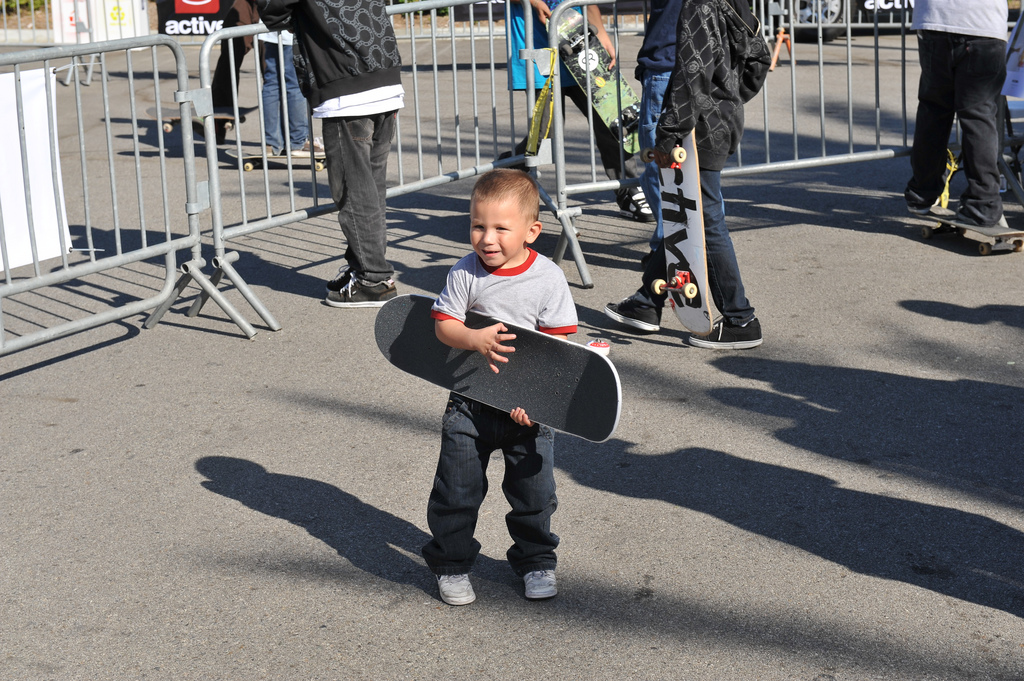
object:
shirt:
[442, 243, 581, 346]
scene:
[0, 0, 1024, 681]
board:
[371, 290, 628, 448]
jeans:
[414, 374, 557, 574]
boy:
[418, 170, 580, 605]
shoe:
[433, 569, 477, 609]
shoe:
[518, 562, 567, 602]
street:
[0, 119, 1024, 681]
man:
[234, 2, 412, 309]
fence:
[0, 35, 272, 367]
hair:
[471, 166, 542, 225]